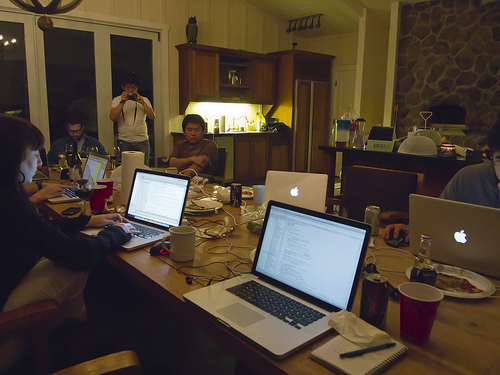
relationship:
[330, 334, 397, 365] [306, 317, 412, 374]
ink pen on notepad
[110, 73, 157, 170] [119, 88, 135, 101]
he holding camera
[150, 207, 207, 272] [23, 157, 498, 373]
mug on top of table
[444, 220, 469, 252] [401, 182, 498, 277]
logo on laptop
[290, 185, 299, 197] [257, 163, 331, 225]
apple on laptop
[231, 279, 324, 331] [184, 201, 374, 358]
keyboard on laptop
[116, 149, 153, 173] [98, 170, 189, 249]
paper towels behind laptop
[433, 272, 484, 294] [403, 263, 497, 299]
pizza on a paper plate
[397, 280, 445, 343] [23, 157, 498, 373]
cup on a table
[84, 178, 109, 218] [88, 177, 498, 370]
cup on a table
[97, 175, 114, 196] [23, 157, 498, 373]
cup on table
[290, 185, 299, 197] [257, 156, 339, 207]
apple on computer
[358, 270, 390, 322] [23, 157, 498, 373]
can on table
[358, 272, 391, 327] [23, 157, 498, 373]
can on table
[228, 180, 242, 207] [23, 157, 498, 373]
can on table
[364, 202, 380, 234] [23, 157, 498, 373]
can on table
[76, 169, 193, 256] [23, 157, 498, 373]
laptop on table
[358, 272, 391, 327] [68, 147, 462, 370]
can on table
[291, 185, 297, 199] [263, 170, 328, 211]
apple on computer